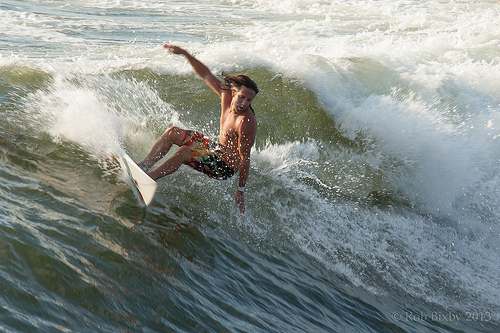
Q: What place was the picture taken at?
A: It was taken at the ocean.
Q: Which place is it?
A: It is an ocean.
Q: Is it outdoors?
A: Yes, it is outdoors.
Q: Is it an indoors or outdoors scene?
A: It is outdoors.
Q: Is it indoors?
A: No, it is outdoors.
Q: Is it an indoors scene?
A: No, it is outdoors.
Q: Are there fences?
A: No, there are no fences.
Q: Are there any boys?
A: No, there are no boys.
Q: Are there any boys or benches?
A: No, there are no boys or benches.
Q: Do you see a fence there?
A: No, there are no fences.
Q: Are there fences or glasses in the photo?
A: No, there are no fences or glasses.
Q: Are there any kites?
A: No, there are no kites.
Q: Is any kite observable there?
A: No, there are no kites.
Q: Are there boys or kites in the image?
A: No, there are no kites or boys.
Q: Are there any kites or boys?
A: No, there are no kites or boys.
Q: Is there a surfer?
A: Yes, there is a surfer.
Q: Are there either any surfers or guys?
A: Yes, there is a surfer.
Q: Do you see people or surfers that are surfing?
A: Yes, the surfer is surfing.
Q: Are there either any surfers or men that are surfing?
A: Yes, the surfer is surfing.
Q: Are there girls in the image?
A: No, there are no girls.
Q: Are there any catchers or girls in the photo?
A: No, there are no girls or catchers.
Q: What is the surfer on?
A: The surfer is on the surfboard.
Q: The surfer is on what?
A: The surfer is on the surfboard.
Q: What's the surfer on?
A: The surfer is on the surfboard.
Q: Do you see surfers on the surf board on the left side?
A: Yes, there is a surfer on the surf board.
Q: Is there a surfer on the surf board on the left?
A: Yes, there is a surfer on the surf board.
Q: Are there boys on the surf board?
A: No, there is a surfer on the surf board.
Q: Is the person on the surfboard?
A: Yes, the surfer is on the surfboard.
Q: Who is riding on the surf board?
A: The surfer is riding on the surf board.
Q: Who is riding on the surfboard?
A: The surfer is riding on the surf board.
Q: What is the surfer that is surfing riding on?
A: The surfer is riding on the surfboard.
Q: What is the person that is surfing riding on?
A: The surfer is riding on the surfboard.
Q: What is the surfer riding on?
A: The surfer is riding on the surfboard.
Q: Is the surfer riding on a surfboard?
A: Yes, the surfer is riding on a surfboard.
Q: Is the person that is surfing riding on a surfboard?
A: Yes, the surfer is riding on a surfboard.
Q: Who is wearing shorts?
A: The surfer is wearing shorts.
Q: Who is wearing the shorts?
A: The surfer is wearing shorts.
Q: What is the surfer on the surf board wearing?
A: The surfer is wearing shorts.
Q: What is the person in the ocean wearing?
A: The surfer is wearing shorts.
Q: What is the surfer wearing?
A: The surfer is wearing shorts.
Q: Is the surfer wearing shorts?
A: Yes, the surfer is wearing shorts.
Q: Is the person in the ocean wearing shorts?
A: Yes, the surfer is wearing shorts.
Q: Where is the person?
A: The surfer is in the ocean.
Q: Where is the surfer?
A: The surfer is in the ocean.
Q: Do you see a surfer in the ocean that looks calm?
A: Yes, there is a surfer in the ocean.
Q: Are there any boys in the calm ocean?
A: No, there is a surfer in the ocean.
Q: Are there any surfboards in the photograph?
A: Yes, there is a surfboard.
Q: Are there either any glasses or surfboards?
A: Yes, there is a surfboard.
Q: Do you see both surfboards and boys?
A: No, there is a surfboard but no boys.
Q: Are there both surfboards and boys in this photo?
A: No, there is a surfboard but no boys.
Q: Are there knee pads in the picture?
A: No, there are no knee pads.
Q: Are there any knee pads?
A: No, there are no knee pads.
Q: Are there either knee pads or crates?
A: No, there are no knee pads or crates.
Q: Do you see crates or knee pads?
A: No, there are no knee pads or crates.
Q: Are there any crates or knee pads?
A: No, there are no knee pads or crates.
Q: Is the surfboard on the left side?
A: Yes, the surfboard is on the left of the image.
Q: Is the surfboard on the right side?
A: No, the surfboard is on the left of the image.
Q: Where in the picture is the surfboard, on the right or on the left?
A: The surfboard is on the left of the image.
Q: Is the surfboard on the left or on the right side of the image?
A: The surfboard is on the left of the image.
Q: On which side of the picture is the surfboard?
A: The surfboard is on the left of the image.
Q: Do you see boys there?
A: No, there are no boys.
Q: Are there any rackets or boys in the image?
A: No, there are no boys or rackets.